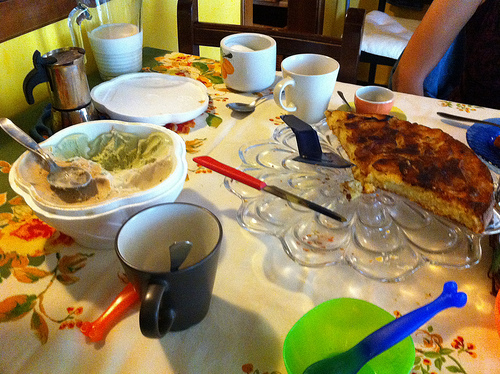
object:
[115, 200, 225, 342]
cup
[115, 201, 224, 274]
white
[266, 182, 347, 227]
dirty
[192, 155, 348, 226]
knife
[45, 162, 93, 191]
dirty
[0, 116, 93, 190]
spoon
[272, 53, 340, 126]
cup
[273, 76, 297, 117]
handle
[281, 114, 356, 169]
black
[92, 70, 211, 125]
plastic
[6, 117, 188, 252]
container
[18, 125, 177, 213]
food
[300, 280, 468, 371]
blue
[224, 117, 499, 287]
glass plate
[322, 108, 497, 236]
food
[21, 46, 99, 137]
container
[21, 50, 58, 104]
handle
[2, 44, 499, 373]
table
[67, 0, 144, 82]
pitcher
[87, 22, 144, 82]
milk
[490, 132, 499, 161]
tart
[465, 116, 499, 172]
plate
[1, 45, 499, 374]
floral pattern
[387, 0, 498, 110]
person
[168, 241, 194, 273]
handle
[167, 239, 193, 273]
spoon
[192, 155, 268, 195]
handle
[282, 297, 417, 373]
green bowl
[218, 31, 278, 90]
white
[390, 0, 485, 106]
arm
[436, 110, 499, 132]
handle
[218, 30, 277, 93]
cups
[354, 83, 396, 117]
cup